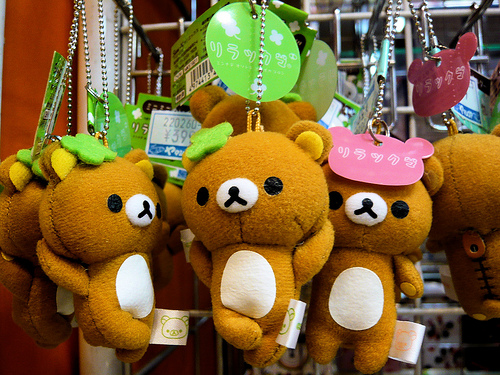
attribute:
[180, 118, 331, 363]
bear — toy, brown, stuffed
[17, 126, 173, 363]
bear — brown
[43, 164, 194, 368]
bear — toy, brown, stuffed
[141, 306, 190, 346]
tag — white, green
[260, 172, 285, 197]
eye — black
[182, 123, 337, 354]
stuffed bear — toy, brown, white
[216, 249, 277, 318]
tummy — white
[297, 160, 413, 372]
bear — toy, stuffed, brown, white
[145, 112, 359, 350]
bear — brown 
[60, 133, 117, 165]
bow — green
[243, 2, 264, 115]
chain — silver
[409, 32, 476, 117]
tag — pink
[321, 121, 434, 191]
tag — pink